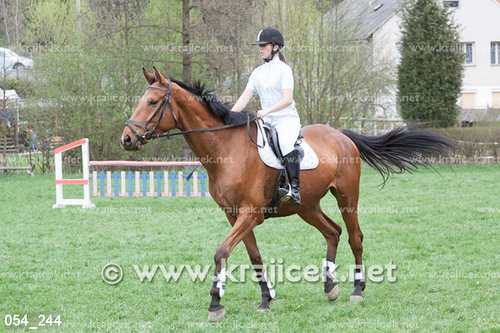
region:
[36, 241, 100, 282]
short green and yellow grass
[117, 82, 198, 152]
brown horse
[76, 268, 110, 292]
short green and yellow grass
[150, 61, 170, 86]
The right ear of the horse.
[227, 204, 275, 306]
The front left leg of the horse.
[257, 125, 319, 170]
The saddle of the horse.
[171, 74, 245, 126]
The mane of the horse.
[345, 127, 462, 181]
The tail of the horse.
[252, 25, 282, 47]
The helmet the girl is wearing.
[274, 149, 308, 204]
The black boot the girl is wearing.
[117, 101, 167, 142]
The harness around the horse's face.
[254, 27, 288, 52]
black helmet with white stripe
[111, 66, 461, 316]
chestnut brown horse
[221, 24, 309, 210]
girl wearing mostly white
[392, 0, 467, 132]
tall cypress shrub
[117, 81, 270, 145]
black bridle and reins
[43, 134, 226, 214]
show jumping equipment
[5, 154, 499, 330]
a lush, wellmanicured lawn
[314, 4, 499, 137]
a mostly white painted house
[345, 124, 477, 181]
a long black horse tail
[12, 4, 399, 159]
a grove of scantily leafed trees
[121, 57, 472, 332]
a brown horse trotting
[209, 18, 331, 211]
a person riding a horse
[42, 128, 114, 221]
a white and red barricade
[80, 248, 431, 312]
a watermark of a photographer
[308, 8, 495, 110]
a large house behind some trees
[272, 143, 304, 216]
a left black boot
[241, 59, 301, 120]
a white shirt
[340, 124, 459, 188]
Black hair coming off a horse.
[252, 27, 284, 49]
Black jockey hat.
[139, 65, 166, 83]
Two brown horse ears.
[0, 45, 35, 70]
A white vehicle.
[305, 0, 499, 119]
A white house with grey roof.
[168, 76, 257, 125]
Black horse mane.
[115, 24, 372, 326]
woman riding brown horse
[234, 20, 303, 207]
rider wearing helmet, white outfit and black boots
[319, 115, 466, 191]
black tail flying in the air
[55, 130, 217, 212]
obstacle composed of poles and slats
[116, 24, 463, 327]
girl riding brown horse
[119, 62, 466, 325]
horse has a black mane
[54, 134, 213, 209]
jumping fence is pink and blue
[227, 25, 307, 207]
girl is wearing a black riding helmet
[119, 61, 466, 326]
horse has a black tail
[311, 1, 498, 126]
tree in front of white house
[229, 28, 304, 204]
girl is wearing a black boot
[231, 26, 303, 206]
girl is wearing a white shirt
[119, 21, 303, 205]
girl is wearing white pants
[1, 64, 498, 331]
horse is trotting on green grass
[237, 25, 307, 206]
the woman is riding a horse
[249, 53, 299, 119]
the woman is wearing a short sleeve shirt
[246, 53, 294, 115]
the shirt is white in color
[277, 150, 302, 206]
the woman is wearing boots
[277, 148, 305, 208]
the boots are made of leather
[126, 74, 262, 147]
the horse is wearing a harness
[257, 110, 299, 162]
the woman is wearing riding pants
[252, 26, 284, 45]
the woman is wearing a hat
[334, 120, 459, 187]
the horse has a black tail